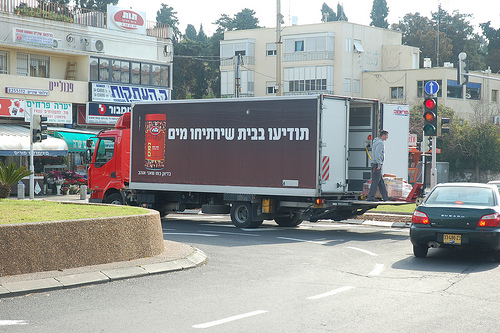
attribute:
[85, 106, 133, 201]
truck — red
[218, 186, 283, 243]
tires — black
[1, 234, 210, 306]
sidewalk — thin, grey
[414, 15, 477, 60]
trees — tall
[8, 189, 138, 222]
grass — green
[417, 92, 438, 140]
traffic light — black